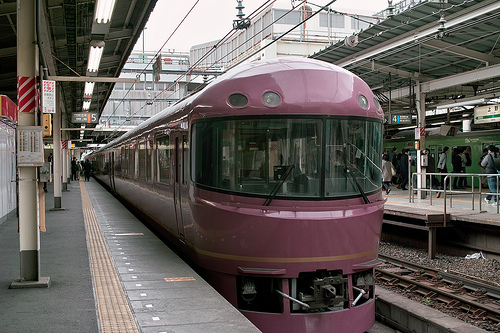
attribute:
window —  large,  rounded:
[189, 116, 384, 199]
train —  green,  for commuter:
[85, 56, 385, 329]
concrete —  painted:
[60, 174, 244, 329]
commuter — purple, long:
[119, 97, 413, 298]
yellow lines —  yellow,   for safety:
[58, 183, 146, 331]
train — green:
[408, 113, 485, 193]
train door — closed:
[142, 104, 214, 234]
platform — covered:
[70, 146, 136, 284]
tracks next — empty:
[387, 225, 498, 323]